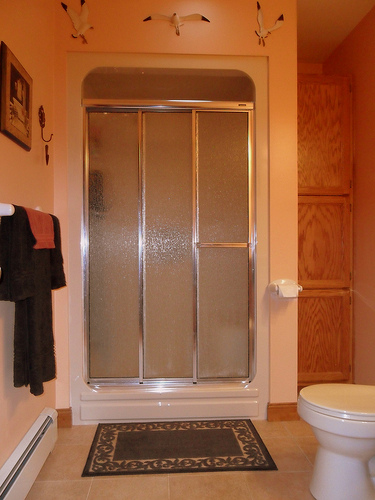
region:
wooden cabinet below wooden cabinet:
[296, 290, 351, 384]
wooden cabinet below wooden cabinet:
[295, 193, 355, 290]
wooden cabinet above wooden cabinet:
[298, 80, 352, 194]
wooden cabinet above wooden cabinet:
[298, 192, 349, 288]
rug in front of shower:
[78, 418, 276, 474]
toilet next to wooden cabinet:
[294, 382, 373, 498]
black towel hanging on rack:
[1, 206, 33, 304]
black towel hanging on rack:
[15, 206, 54, 396]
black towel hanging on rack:
[51, 212, 67, 290]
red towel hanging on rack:
[17, 207, 53, 249]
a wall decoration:
[140, 9, 212, 36]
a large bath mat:
[78, 414, 278, 479]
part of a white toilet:
[297, 384, 374, 498]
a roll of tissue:
[277, 283, 298, 303]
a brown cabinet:
[293, 290, 351, 383]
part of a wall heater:
[0, 405, 61, 498]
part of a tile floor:
[34, 475, 312, 498]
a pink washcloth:
[24, 202, 57, 248]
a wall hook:
[40, 108, 55, 144]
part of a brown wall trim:
[269, 399, 299, 422]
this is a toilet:
[292, 373, 371, 494]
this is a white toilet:
[295, 369, 372, 489]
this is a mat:
[83, 413, 278, 474]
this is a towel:
[10, 206, 61, 396]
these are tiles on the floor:
[82, 471, 309, 498]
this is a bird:
[56, 3, 106, 53]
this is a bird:
[139, 7, 224, 31]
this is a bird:
[248, 0, 291, 47]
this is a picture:
[1, 40, 35, 153]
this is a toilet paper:
[269, 278, 306, 301]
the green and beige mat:
[80, 408, 286, 493]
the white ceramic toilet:
[287, 369, 373, 493]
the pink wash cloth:
[21, 200, 61, 257]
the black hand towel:
[5, 203, 38, 309]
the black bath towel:
[11, 211, 63, 408]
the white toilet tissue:
[276, 285, 302, 306]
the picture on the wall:
[1, 35, 43, 159]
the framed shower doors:
[77, 92, 259, 393]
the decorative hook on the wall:
[39, 100, 57, 150]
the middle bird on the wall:
[142, 6, 217, 47]